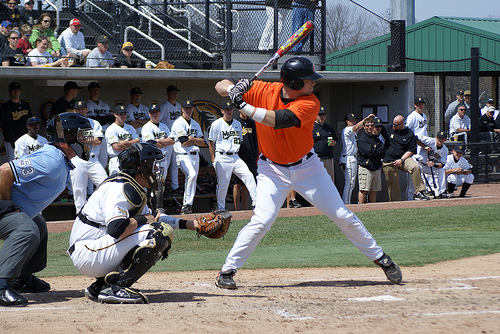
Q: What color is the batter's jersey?
A: Orange.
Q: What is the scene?
A: A baseball game in the daytime.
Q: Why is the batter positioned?
A: He is about to hit the ball.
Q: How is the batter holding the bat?
A: With two hands.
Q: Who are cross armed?
A: The players.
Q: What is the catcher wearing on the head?
A: A helmet.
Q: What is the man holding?
A: A baseball bat.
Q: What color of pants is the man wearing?
A: White.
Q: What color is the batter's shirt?
A: Orange.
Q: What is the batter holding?
A: A bat.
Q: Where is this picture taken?
A: A baseball field.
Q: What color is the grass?
A: Green.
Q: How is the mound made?
A: Of dirt.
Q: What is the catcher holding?
A: A mitt.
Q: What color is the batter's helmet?
A: Black.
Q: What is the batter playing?
A: Baseball.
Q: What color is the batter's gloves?
A: Black.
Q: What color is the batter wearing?
A: Orange.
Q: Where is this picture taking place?
A: Baseball field.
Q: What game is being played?
A: Baseball.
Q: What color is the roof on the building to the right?
A: Green.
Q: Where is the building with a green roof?
A: On the right.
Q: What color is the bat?
A: Orange.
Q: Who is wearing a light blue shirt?
A: The man on the far left.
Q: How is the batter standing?
A: With his legs apart.